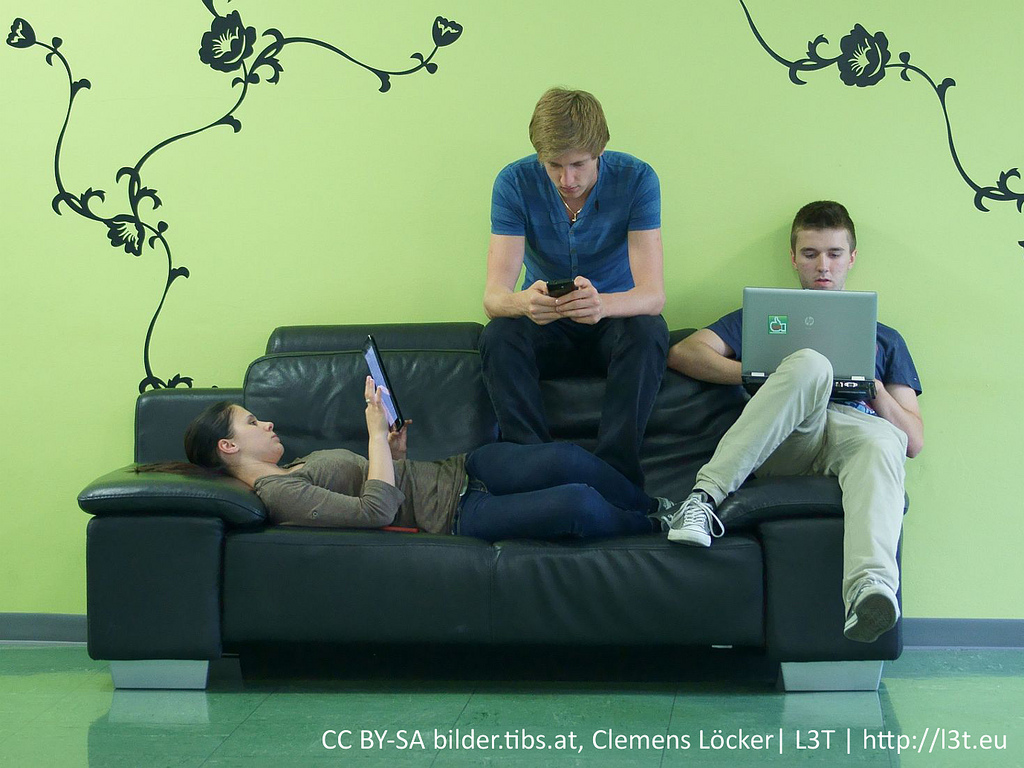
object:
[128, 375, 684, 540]
people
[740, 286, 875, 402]
gadget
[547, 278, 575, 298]
gadget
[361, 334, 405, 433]
gadget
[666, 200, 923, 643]
man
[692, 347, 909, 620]
pants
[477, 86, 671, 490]
man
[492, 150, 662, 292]
shirt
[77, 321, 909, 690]
sofa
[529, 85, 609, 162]
hair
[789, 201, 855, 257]
hair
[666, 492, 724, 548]
shoe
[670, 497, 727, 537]
shoelace